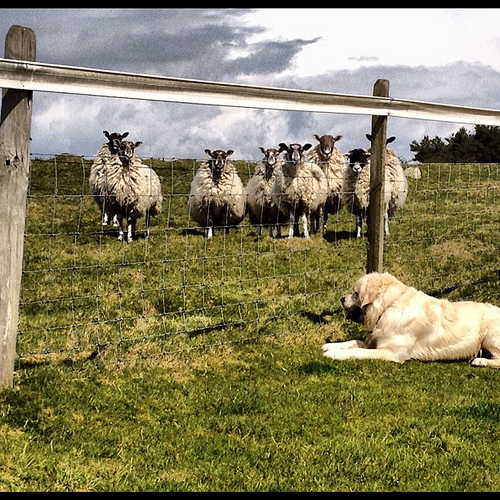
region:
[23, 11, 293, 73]
Dark and cloudy day.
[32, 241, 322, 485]
Green grass to feed the sheep.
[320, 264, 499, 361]
A dog guarding the sheep.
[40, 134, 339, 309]
Chicken wire fence.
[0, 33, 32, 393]
Wood pole supporting the fences.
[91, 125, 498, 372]
Dog and sheep are looking at each other.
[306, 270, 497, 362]
Brownish and white dog.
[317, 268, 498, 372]
Dog sitting on the ground.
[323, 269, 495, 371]
Dog intensely watching the ship.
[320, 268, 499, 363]
Good and obedient dog.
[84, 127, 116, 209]
white sheep in field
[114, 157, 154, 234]
white sheep in field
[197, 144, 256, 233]
white sheep in field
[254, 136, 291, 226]
white sheep in field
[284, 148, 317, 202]
white sheep in field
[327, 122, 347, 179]
white sheep in field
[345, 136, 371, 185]
white sheep in field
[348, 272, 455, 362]
sheep dog by fence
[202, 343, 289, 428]
grass growing on field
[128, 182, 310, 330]
wire fence in front of dog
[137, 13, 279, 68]
thick gray clouds hovering overheas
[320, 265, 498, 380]
a fluffy white dog lying down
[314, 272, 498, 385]
a dog watching sheep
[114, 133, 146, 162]
black head on a fluffy white sheep body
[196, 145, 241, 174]
black head on a fluffy white sheep body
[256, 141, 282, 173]
black head on a fluffy white sheep body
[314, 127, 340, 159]
black head on a fluffy white sheep body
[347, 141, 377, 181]
black head on a fluffy white sheep body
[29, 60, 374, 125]
a white metal railing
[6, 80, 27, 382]
a wooden fence support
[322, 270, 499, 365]
A cream colored dog laying down.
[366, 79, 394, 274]
A wooden fence post.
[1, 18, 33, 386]
A brown wooden post.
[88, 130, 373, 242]
A small flock of sheep.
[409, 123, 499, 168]
A distant group of trees.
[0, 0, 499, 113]
A background of gray cloudy sky.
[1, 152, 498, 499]
A large green pasture.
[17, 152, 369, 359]
A piece of wire fencing.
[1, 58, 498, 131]
A white fence rail.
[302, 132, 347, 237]
A sheep with a brown head.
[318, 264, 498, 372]
dog is laying on grass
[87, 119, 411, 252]
a bunch of sheeps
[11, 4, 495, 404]
dog is watching over the sheeps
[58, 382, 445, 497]
green plain field of grass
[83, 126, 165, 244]
two sheep standing tall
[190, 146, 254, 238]
a sheep standing tall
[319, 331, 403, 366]
paws of a dog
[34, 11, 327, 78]
could in the sky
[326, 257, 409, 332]
head of a dog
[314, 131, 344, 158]
head of a sheep